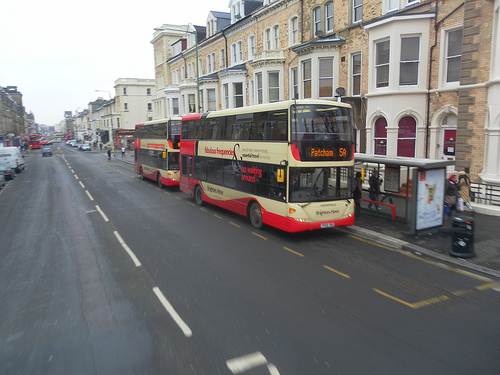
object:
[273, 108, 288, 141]
windows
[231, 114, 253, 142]
windows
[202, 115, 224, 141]
windows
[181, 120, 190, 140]
windows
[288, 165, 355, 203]
windshield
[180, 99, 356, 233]
bus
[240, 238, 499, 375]
street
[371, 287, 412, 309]
yellow line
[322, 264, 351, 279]
yellow line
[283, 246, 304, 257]
yellow line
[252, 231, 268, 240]
yellow line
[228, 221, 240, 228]
yellow line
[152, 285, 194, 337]
line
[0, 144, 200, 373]
street